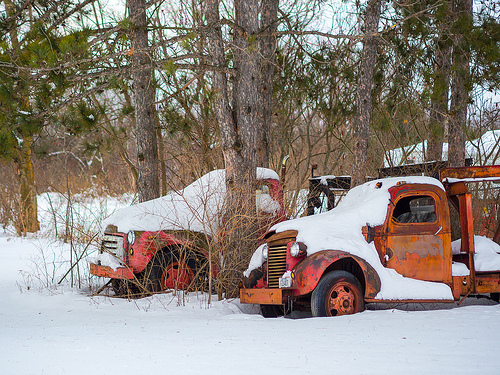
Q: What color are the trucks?
A: Red.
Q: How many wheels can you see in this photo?
A: 4.